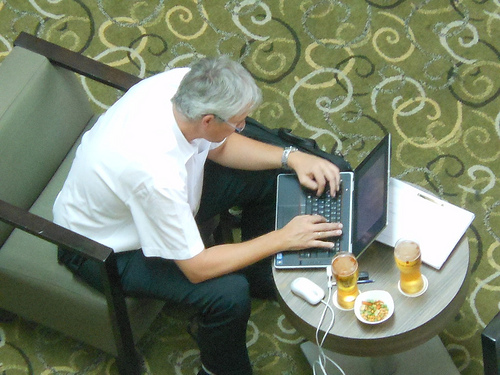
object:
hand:
[291, 152, 348, 193]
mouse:
[288, 273, 328, 307]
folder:
[372, 175, 474, 271]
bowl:
[351, 290, 393, 325]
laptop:
[271, 129, 395, 272]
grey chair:
[0, 45, 135, 369]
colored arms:
[0, 200, 145, 367]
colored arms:
[11, 27, 135, 100]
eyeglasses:
[215, 107, 250, 127]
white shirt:
[48, 67, 227, 262]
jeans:
[55, 157, 287, 372]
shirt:
[50, 62, 229, 264]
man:
[51, 52, 345, 373]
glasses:
[194, 102, 250, 136]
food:
[360, 300, 388, 320]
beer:
[385, 234, 442, 298]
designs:
[347, 60, 459, 142]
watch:
[269, 139, 305, 171]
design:
[4, 1, 495, 373]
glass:
[391, 235, 425, 295]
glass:
[331, 253, 365, 307]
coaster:
[397, 275, 430, 298]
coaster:
[331, 287, 361, 311]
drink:
[395, 252, 425, 294]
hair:
[170, 48, 265, 125]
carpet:
[0, 3, 495, 371]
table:
[270, 167, 471, 372]